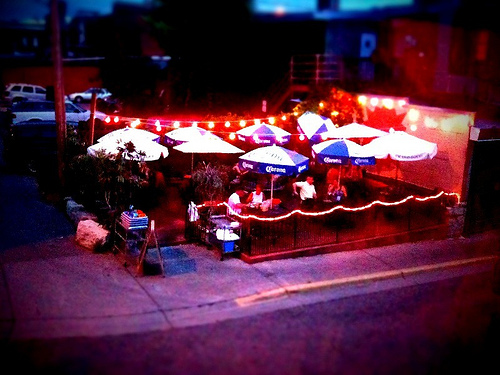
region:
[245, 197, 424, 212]
lights on the gate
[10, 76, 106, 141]
the cars are parked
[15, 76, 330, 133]
cars behind the picnic area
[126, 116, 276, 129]
the lights on astring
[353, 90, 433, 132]
the lights are lit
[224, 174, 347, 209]
the people are sitting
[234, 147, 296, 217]
people under the umbrella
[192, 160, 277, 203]
plant behind the people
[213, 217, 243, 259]
trash bag in the can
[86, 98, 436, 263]
outdoor restaurant with many blue and white umbrellas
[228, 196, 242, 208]
man sitting and dining in white shirt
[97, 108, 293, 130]
string of lights lining patio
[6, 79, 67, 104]
white SUV parked on street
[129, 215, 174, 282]
advertising placard on sidewalk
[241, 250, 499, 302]
light curb on grey sidewalk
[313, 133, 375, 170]
blue and white umbrella advertising Cinzano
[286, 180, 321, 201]
man with arm bent over chair wearing white shirt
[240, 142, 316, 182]
blue and white Corona umbrella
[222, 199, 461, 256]
fence with red rope lights at the top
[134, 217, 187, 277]
sandwich cafe board on a sidewalk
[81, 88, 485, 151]
red lights above an outdoor cafe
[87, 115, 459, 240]
an outdoor cafe with people eating under umbrellas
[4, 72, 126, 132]
parked cars in a parking lot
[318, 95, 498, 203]
exterior wall to a building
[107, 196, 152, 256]
bus bin outside on a table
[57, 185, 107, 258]
large rocks lining a driveway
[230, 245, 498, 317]
empty sidewalk with yellow paint on the currb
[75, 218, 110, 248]
Rock sitting near a sidewalk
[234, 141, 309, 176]
Umbrella at a cafe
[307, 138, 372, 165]
Umbrella at a cafe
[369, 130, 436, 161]
White umbrella at a cafe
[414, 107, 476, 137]
blurry yellow lights on a wall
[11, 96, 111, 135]
white pickup truck parked in lot behind outdoor cafe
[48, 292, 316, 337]
sloped concrete street access curb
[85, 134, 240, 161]
white overhead table umbrellas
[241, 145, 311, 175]
square white and blue table umbrella with pointy top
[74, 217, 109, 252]
small wooden block on sidewalk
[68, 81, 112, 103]
park small silver car near wall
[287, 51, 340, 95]
top platform of metal staircase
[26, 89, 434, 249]
umbrellas over the land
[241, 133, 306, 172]
top of the umbrella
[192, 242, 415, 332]
sidewalk next to street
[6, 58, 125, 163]
many cars on the ground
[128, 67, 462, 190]
lights above the umbrellas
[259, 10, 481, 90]
building next to the umbrellas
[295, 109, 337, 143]
Blue and white tipped umbrella.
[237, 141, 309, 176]
Blue and white umbrella over a man and woman in white shirts.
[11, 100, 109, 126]
A white parked truck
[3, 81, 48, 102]
A white parked suv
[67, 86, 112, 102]
White parked car in front of a white suv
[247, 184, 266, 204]
A woman in a white shirt.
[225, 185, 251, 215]
A man in a white shirt with a black hat on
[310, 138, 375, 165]
Blue and white umbrella over a woman in blue and man in white